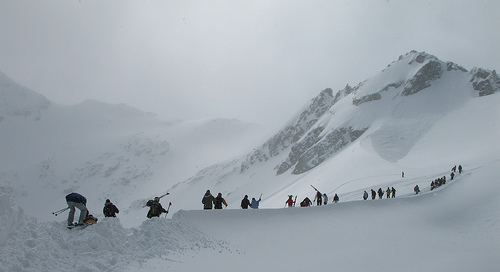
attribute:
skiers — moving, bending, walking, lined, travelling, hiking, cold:
[36, 175, 431, 209]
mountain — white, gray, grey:
[331, 75, 485, 205]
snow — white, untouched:
[99, 128, 210, 179]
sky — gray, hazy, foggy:
[84, 15, 291, 66]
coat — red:
[286, 194, 311, 215]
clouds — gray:
[88, 43, 270, 165]